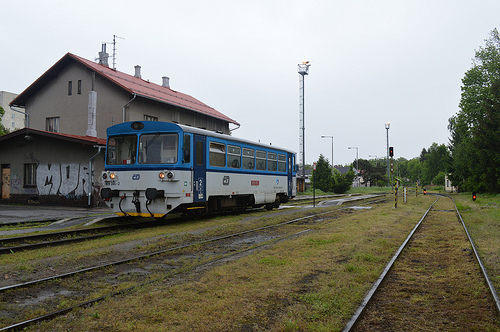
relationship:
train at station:
[100, 120, 306, 219] [5, 47, 346, 226]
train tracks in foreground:
[32, 230, 492, 304] [26, 196, 448, 302]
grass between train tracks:
[223, 239, 338, 308] [32, 230, 492, 304]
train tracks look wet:
[32, 230, 492, 304] [355, 290, 373, 308]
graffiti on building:
[34, 167, 94, 207] [7, 71, 190, 202]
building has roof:
[7, 71, 190, 202] [23, 50, 231, 114]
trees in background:
[374, 63, 490, 184] [291, 51, 499, 209]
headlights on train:
[101, 167, 183, 182] [100, 120, 301, 204]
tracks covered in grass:
[80, 227, 381, 321] [223, 239, 338, 308]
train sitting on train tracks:
[100, 120, 301, 204] [32, 230, 492, 304]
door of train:
[193, 135, 206, 205] [100, 120, 301, 204]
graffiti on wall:
[34, 167, 94, 207] [12, 141, 101, 205]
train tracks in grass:
[32, 230, 492, 304] [223, 239, 338, 308]